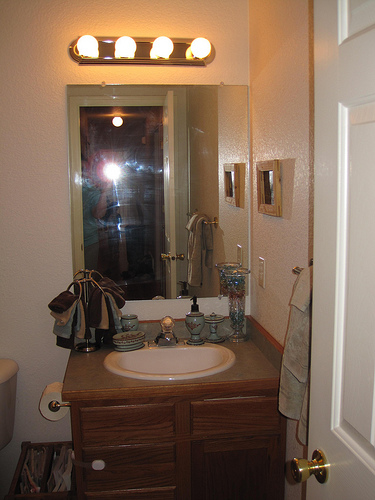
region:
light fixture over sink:
[68, 33, 216, 63]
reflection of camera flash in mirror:
[97, 153, 121, 184]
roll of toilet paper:
[40, 381, 67, 420]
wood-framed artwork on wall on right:
[255, 154, 282, 223]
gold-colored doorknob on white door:
[288, 441, 329, 486]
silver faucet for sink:
[148, 316, 185, 347]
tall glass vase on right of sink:
[218, 259, 256, 343]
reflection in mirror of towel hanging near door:
[187, 203, 218, 289]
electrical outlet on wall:
[254, 253, 271, 291]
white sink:
[104, 349, 241, 379]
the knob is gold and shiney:
[283, 451, 329, 484]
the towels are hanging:
[276, 274, 302, 426]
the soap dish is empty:
[107, 327, 147, 351]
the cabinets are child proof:
[70, 450, 117, 477]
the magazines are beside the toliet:
[50, 454, 65, 484]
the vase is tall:
[218, 268, 259, 343]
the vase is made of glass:
[217, 262, 256, 344]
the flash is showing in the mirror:
[94, 156, 125, 188]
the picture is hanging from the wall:
[253, 159, 280, 216]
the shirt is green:
[81, 177, 101, 242]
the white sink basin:
[102, 341, 235, 377]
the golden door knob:
[285, 446, 331, 480]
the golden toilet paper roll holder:
[50, 400, 69, 410]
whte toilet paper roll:
[38, 383, 69, 413]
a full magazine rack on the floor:
[10, 437, 77, 498]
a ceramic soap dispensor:
[186, 294, 203, 342]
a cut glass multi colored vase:
[225, 267, 249, 339]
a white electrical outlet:
[257, 254, 267, 288]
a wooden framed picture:
[253, 159, 283, 215]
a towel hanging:
[184, 212, 210, 283]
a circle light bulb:
[74, 32, 102, 58]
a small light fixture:
[64, 30, 215, 64]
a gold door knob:
[278, 448, 332, 486]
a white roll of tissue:
[37, 375, 67, 423]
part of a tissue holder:
[48, 400, 67, 411]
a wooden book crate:
[6, 434, 73, 498]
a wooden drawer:
[190, 396, 280, 435]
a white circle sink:
[102, 345, 248, 378]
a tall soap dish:
[183, 291, 207, 344]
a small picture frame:
[252, 157, 287, 219]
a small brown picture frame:
[252, 158, 290, 219]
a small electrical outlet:
[253, 255, 268, 289]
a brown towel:
[48, 288, 76, 311]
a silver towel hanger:
[65, 280, 81, 300]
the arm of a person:
[87, 183, 110, 219]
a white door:
[303, 0, 373, 498]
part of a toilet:
[0, 353, 20, 448]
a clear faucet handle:
[157, 315, 172, 330]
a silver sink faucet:
[150, 315, 184, 346]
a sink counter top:
[61, 317, 286, 390]